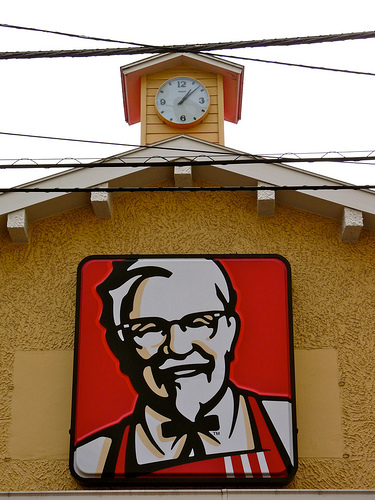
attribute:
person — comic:
[73, 258, 289, 478]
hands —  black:
[181, 88, 204, 106]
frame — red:
[85, 259, 288, 473]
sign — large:
[72, 251, 301, 484]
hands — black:
[176, 86, 204, 103]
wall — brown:
[185, 190, 286, 238]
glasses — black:
[118, 310, 225, 348]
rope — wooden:
[0, 27, 374, 59]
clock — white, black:
[156, 74, 209, 125]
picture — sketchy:
[77, 255, 288, 473]